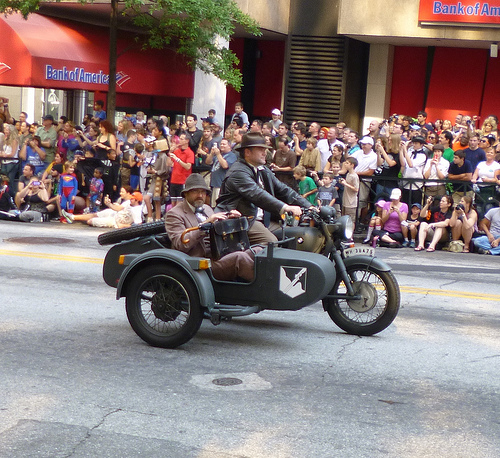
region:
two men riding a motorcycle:
[92, 139, 394, 352]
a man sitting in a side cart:
[138, 180, 303, 293]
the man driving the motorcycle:
[225, 140, 318, 227]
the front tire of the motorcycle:
[334, 256, 399, 334]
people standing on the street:
[13, 105, 498, 257]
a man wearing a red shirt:
[170, 140, 190, 185]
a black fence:
[357, 173, 498, 231]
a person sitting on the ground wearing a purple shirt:
[384, 193, 410, 243]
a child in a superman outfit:
[56, 163, 74, 220]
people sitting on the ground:
[373, 195, 494, 246]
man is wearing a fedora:
[225, 118, 284, 185]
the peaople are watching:
[80, 89, 499, 268]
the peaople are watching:
[45, 93, 317, 224]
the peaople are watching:
[50, 102, 203, 251]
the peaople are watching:
[145, 89, 375, 248]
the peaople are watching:
[134, 96, 230, 227]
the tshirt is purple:
[383, 201, 403, 229]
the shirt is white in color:
[403, 150, 447, 173]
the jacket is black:
[223, 159, 300, 222]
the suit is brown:
[171, 212, 265, 270]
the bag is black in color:
[209, 222, 258, 257]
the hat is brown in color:
[236, 127, 277, 149]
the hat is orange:
[129, 191, 146, 202]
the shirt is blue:
[461, 148, 484, 163]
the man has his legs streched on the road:
[88, 198, 148, 225]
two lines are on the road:
[423, 282, 482, 304]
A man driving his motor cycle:
[105, 135, 404, 352]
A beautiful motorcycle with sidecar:
[108, 128, 399, 350]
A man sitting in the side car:
[100, 132, 396, 343]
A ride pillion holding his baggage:
[106, 125, 402, 331]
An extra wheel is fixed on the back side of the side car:
[99, 128, 453, 358]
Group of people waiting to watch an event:
[11, 95, 497, 253]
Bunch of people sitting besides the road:
[5, 108, 495, 249]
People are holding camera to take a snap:
[5, 105, 497, 273]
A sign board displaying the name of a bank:
[20, 0, 496, 142]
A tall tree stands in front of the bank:
[105, 3, 262, 200]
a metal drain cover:
[209, 371, 248, 391]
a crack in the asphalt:
[62, 402, 147, 445]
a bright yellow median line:
[14, 246, 85, 267]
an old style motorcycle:
[97, 191, 406, 361]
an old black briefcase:
[207, 213, 253, 258]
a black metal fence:
[334, 166, 499, 212]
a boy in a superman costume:
[53, 158, 84, 224]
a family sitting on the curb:
[358, 185, 439, 247]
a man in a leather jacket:
[216, 126, 323, 249]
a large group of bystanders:
[18, 92, 495, 244]